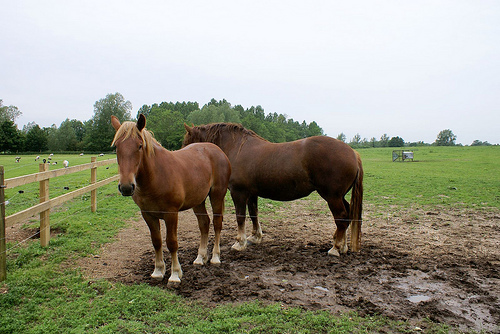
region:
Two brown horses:
[93, 101, 385, 295]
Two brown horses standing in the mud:
[100, 102, 482, 313]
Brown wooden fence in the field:
[5, 152, 137, 256]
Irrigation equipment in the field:
[385, 143, 422, 171]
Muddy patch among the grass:
[138, 234, 493, 325]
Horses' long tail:
[342, 137, 377, 262]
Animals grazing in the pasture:
[7, 134, 101, 179]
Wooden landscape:
[12, 87, 403, 155]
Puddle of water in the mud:
[400, 286, 444, 309]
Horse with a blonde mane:
[92, 102, 177, 230]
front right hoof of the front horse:
[144, 268, 162, 284]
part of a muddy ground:
[320, 263, 435, 305]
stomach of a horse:
[179, 155, 209, 206]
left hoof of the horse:
[164, 273, 178, 286]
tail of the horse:
[351, 183, 373, 243]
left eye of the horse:
[130, 132, 145, 153]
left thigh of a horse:
[328, 170, 345, 207]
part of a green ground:
[433, 153, 486, 193]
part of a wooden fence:
[18, 162, 89, 225]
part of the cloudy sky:
[118, 16, 348, 108]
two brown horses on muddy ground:
[105, 105, 365, 290]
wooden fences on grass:
[1, 158, 116, 257]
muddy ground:
[130, 234, 496, 320]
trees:
[0, 89, 387, 146]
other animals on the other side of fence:
[1, 96, 108, 242]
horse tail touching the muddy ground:
[332, 120, 379, 260]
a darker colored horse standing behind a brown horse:
[183, 115, 376, 265]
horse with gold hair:
[102, 110, 169, 197]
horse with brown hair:
[175, 119, 272, 154]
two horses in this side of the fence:
[2, 85, 499, 297]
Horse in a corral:
[82, 104, 238, 289]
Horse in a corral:
[176, 111, 381, 271]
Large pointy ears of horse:
[100, 102, 151, 138]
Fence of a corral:
[8, 136, 123, 247]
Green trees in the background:
[1, 91, 329, 149]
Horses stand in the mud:
[100, 98, 492, 298]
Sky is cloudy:
[3, 3, 499, 100]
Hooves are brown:
[146, 274, 181, 294]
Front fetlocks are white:
[147, 259, 189, 279]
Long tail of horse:
[346, 149, 373, 257]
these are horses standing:
[107, 113, 364, 261]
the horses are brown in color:
[103, 106, 379, 264]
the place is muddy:
[241, 252, 461, 320]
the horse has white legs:
[146, 232, 218, 274]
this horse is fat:
[238, 141, 368, 228]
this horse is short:
[240, 134, 350, 254]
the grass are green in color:
[392, 162, 476, 192]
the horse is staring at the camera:
[106, 126, 146, 191]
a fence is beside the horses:
[4, 161, 96, 241]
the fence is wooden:
[0, 161, 97, 247]